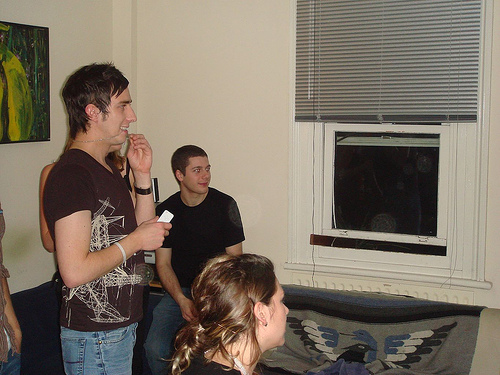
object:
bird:
[286, 317, 460, 374]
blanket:
[370, 323, 451, 347]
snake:
[339, 329, 377, 363]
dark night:
[356, 149, 419, 216]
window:
[330, 131, 440, 236]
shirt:
[156, 187, 246, 288]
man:
[142, 144, 245, 372]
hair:
[162, 253, 275, 375]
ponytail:
[157, 309, 209, 373]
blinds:
[294, 0, 481, 122]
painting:
[0, 20, 50, 144]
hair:
[171, 144, 209, 184]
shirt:
[43, 148, 145, 332]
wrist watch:
[134, 185, 152, 195]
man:
[42, 60, 172, 375]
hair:
[62, 61, 131, 140]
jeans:
[58, 322, 139, 372]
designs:
[61, 196, 144, 327]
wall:
[0, 0, 499, 313]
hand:
[135, 216, 172, 251]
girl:
[157, 252, 289, 374]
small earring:
[265, 324, 267, 327]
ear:
[254, 302, 269, 326]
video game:
[157, 210, 174, 223]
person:
[0, 207, 23, 374]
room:
[1, 1, 500, 374]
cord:
[312, 1, 315, 287]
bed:
[0, 281, 499, 375]